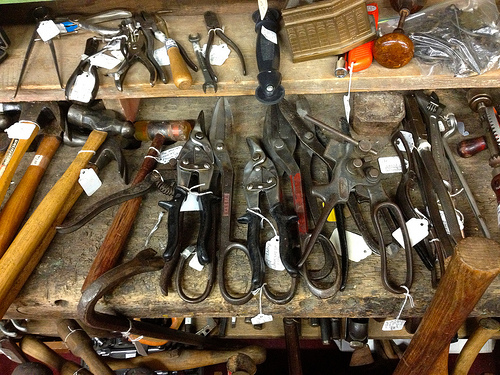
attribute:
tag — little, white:
[389, 210, 449, 261]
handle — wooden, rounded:
[418, 250, 488, 357]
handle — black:
[157, 190, 184, 260]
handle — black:
[196, 192, 222, 264]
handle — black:
[237, 211, 268, 286]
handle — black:
[272, 204, 301, 276]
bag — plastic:
[418, 12, 488, 62]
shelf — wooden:
[3, 103, 499, 320]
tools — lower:
[218, 169, 358, 266]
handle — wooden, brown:
[8, 143, 97, 286]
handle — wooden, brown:
[8, 132, 64, 237]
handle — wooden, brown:
[1, 128, 39, 206]